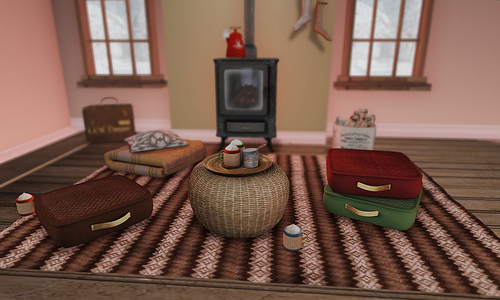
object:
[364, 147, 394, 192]
ground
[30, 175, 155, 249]
suitcase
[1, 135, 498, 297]
rug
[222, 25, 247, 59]
red kettle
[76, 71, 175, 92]
window sill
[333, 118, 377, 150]
white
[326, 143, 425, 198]
pillow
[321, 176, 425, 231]
pillow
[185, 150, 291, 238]
ottoman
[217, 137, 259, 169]
cups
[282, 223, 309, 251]
cups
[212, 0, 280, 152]
stove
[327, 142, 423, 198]
suitcase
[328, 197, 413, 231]
green item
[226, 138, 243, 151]
whipped cream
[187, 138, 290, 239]
basket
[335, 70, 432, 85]
windowsill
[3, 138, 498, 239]
hardwood floor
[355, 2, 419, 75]
forest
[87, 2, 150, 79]
window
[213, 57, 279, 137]
fireplace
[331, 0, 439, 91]
wooden frame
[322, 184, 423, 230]
container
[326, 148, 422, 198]
container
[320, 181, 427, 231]
suitcase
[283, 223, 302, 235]
whipped cream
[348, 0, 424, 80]
window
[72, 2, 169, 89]
frame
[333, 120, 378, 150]
box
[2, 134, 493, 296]
floor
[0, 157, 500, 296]
stripe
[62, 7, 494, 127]
wall